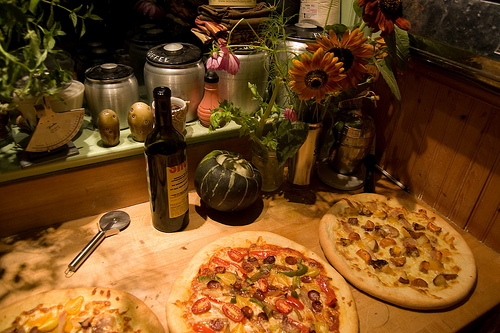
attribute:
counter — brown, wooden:
[7, 112, 500, 333]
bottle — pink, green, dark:
[149, 86, 193, 236]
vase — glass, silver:
[235, 93, 381, 187]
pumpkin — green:
[199, 150, 262, 213]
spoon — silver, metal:
[65, 203, 132, 274]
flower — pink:
[209, 31, 406, 122]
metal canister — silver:
[24, 32, 350, 112]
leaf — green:
[374, 44, 418, 100]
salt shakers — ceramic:
[94, 105, 160, 149]